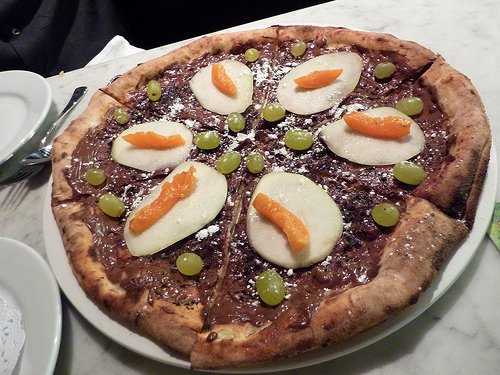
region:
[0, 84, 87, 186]
fork and a spoon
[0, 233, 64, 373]
coffee cup plate with doily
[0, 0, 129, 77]
black shirt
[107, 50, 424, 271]
orange puree on a slice of something white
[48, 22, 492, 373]
chocolate and fruit pizza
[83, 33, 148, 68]
white napkin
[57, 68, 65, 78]
crumb of food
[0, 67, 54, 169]
regular plate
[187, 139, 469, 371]
a slice of fruit pizza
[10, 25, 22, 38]
black button from a shirt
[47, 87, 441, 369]
the plate is white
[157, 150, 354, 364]
the plate is white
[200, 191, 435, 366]
the plate is white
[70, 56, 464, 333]
the pie is sliced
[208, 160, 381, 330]
the sauce is chocolate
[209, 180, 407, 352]
the chocolate is brown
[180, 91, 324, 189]
the grapes are green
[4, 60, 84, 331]
plate on the table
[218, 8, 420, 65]
the table is made of marble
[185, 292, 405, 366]
the crust is brown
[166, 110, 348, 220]
grapes on top of a pie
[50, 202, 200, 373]
the crust is baked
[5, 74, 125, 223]
utensils beside the pie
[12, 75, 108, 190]
A shiny silver spoon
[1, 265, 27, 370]
Decorative paper on top of a plate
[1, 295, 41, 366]
The paper is white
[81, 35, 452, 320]
Green grapes on top of the pizza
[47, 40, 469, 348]
The pizza is on a white round plate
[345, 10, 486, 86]
The counter is white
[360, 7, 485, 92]
The counter has grey streaks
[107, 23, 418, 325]
There is a white powder on top of the pizza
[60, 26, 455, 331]
The pizza is brown, green, orange, and white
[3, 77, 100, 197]
A silver fork on the counter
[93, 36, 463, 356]
round pizza on a white plate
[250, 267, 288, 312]
green grape on pizza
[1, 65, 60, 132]
white plate on table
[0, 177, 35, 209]
shadow of a fork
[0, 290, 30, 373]
white doily on a plate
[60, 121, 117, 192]
chocolate sauce on a pizza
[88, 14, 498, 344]
large dessert pizza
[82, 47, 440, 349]
pizza with chocolate sauce and grapes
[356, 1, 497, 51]
white marble table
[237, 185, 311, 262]
orange pizza topping